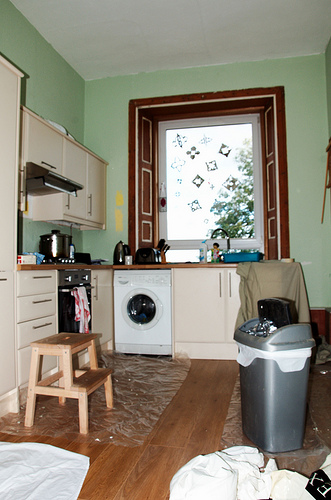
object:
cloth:
[172, 445, 307, 500]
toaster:
[134, 247, 160, 263]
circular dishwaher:
[123, 288, 163, 327]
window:
[124, 94, 281, 255]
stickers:
[185, 196, 204, 216]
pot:
[39, 230, 73, 258]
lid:
[34, 229, 73, 237]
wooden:
[25, 330, 114, 435]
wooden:
[192, 358, 228, 408]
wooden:
[172, 410, 215, 436]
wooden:
[70, 440, 101, 453]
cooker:
[38, 221, 72, 266]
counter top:
[19, 261, 296, 268]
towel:
[70, 287, 95, 332]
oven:
[54, 266, 97, 338]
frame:
[156, 121, 268, 259]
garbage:
[246, 316, 276, 340]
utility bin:
[222, 250, 262, 261]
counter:
[17, 260, 301, 268]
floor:
[0, 342, 331, 500]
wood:
[85, 373, 219, 499]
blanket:
[0, 439, 90, 499]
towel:
[325, 136, 331, 193]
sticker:
[185, 146, 200, 159]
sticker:
[217, 142, 231, 157]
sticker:
[197, 133, 212, 146]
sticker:
[171, 132, 188, 148]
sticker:
[191, 174, 205, 188]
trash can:
[232, 297, 318, 453]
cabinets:
[20, 103, 110, 231]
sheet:
[0, 440, 83, 498]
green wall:
[88, 75, 121, 143]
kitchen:
[0, 0, 331, 499]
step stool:
[21, 326, 119, 431]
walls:
[290, 65, 321, 170]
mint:
[192, 69, 241, 84]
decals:
[190, 174, 205, 189]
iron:
[113, 240, 130, 267]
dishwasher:
[113, 262, 173, 356]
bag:
[236, 337, 320, 374]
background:
[1, 1, 331, 310]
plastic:
[2, 347, 193, 442]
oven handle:
[56, 278, 93, 299]